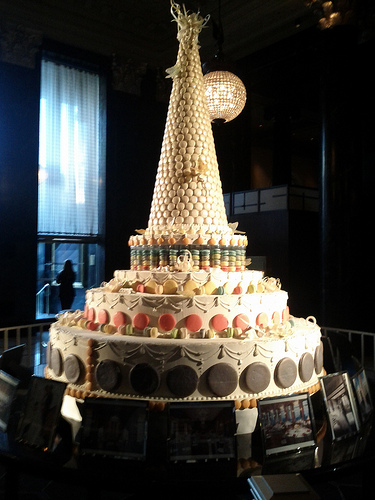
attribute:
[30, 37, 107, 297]
curtain — sheer, white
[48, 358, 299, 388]
cookies — black, round, brown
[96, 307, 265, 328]
candies — orange, round, pink, red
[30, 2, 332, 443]
cake — tan, pointed, large, white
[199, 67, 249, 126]
bulb — hanging, round, white, disco ball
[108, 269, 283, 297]
candies — yellow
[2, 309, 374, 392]
fencing — white